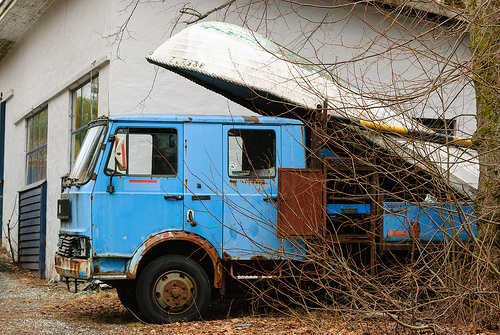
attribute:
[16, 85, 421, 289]
truck — blue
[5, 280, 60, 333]
gravel — grey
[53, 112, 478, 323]
truck — blue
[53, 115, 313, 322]
cab — blue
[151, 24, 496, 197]
boat — white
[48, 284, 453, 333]
leaves — fallen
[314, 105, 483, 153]
pole — yellow, black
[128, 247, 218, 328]
wheel — rusted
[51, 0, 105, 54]
walls — white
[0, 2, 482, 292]
building — white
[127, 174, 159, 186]
stripe — red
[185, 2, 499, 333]
branches — many, dried out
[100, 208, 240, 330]
tire — black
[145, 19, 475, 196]
boat — white